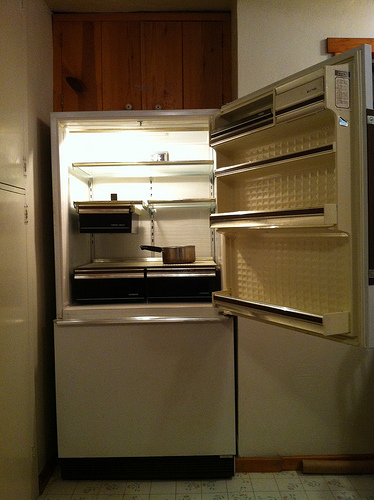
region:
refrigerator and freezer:
[52, 47, 360, 481]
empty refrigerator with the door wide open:
[57, 64, 366, 477]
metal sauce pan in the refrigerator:
[141, 241, 194, 263]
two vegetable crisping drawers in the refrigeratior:
[78, 271, 215, 303]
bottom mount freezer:
[58, 317, 236, 457]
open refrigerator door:
[213, 50, 367, 346]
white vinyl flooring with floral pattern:
[46, 472, 372, 497]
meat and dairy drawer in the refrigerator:
[73, 205, 138, 231]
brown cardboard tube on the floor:
[300, 459, 372, 477]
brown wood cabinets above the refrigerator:
[57, 18, 227, 108]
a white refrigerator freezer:
[48, 44, 372, 482]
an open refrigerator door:
[207, 45, 367, 351]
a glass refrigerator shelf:
[70, 160, 213, 178]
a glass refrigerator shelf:
[147, 197, 213, 209]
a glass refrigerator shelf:
[73, 255, 214, 272]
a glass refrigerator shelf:
[71, 198, 147, 214]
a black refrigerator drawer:
[75, 204, 137, 232]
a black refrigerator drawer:
[71, 269, 143, 301]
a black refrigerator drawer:
[146, 271, 218, 301]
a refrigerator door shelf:
[213, 140, 334, 177]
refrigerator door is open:
[186, 180, 256, 214]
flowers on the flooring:
[263, 476, 320, 499]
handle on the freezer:
[117, 306, 173, 333]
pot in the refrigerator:
[152, 219, 191, 254]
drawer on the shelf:
[93, 202, 137, 241]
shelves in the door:
[287, 149, 328, 166]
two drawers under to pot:
[129, 266, 176, 294]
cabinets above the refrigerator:
[113, 68, 177, 100]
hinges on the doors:
[9, 144, 42, 224]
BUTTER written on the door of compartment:
[305, 79, 330, 100]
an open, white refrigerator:
[37, 41, 373, 481]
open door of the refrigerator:
[207, 43, 372, 350]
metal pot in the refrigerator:
[138, 243, 195, 264]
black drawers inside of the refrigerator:
[75, 204, 218, 303]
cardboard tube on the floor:
[300, 458, 373, 476]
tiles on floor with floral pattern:
[37, 468, 373, 498]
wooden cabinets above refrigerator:
[52, 14, 232, 112]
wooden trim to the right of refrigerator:
[325, 35, 372, 55]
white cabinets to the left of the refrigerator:
[0, 0, 41, 499]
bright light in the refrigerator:
[64, 133, 156, 162]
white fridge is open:
[50, 108, 357, 455]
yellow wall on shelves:
[221, 149, 319, 279]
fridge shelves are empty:
[239, 160, 339, 311]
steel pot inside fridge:
[142, 234, 197, 269]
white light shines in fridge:
[62, 128, 205, 196]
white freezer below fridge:
[56, 314, 229, 451]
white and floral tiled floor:
[56, 469, 328, 497]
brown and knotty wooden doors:
[61, 27, 228, 106]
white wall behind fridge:
[250, 13, 367, 90]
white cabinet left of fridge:
[0, 119, 40, 274]